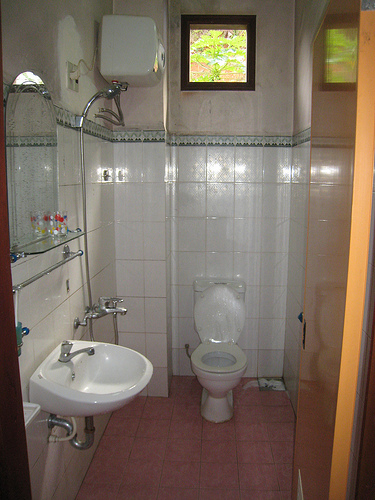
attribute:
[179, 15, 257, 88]
window — framed, small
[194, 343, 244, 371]
toilet seat — white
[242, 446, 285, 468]
tile — square, red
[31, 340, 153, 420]
sink — white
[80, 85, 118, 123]
shower head — silver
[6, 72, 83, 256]
mirror — curved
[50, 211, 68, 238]
cup — glass, colorful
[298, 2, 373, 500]
door — brown, open, yellow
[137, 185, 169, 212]
tile — square, white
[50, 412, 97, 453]
pipe — metal, drainage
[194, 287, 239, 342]
lid — up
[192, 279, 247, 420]
bathroom toilet — white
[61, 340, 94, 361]
faucet — chrome, large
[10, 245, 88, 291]
towel rack — metal